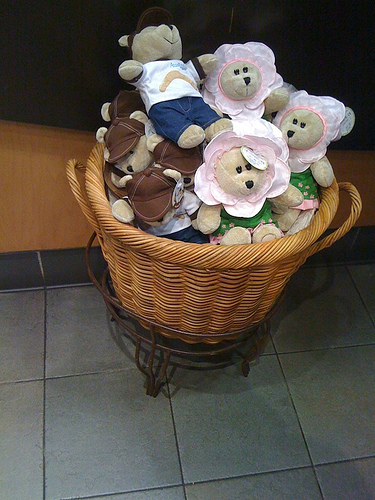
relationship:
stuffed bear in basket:
[202, 33, 285, 118] [60, 126, 356, 364]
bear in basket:
[268, 83, 361, 234] [58, 128, 318, 362]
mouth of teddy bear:
[237, 190, 259, 196] [192, 129, 302, 245]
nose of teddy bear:
[124, 164, 134, 172] [122, 164, 136, 174]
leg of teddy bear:
[111, 191, 137, 221] [98, 105, 174, 220]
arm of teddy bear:
[195, 201, 227, 233] [192, 129, 302, 245]